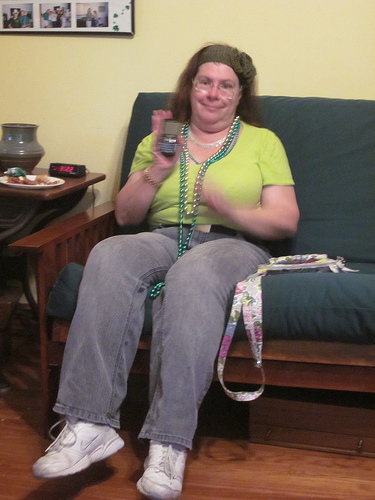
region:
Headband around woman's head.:
[200, 37, 264, 96]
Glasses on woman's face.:
[194, 73, 262, 117]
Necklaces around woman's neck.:
[177, 134, 221, 239]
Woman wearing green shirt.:
[205, 159, 258, 197]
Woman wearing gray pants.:
[73, 358, 204, 415]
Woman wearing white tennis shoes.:
[54, 423, 181, 482]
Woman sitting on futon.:
[108, 204, 297, 348]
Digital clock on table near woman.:
[53, 155, 99, 191]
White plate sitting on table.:
[8, 171, 59, 200]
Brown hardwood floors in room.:
[216, 443, 278, 478]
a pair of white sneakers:
[28, 411, 197, 499]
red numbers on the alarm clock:
[53, 160, 74, 176]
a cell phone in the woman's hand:
[156, 114, 186, 163]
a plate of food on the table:
[0, 171, 66, 192]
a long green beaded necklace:
[137, 113, 243, 303]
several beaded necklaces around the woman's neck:
[143, 111, 241, 304]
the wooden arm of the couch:
[4, 185, 119, 261]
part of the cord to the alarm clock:
[87, 175, 98, 214]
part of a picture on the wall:
[0, 0, 139, 46]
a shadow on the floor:
[14, 453, 120, 498]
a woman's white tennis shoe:
[133, 435, 191, 497]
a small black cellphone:
[156, 113, 183, 158]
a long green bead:
[146, 112, 238, 298]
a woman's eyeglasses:
[188, 69, 243, 103]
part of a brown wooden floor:
[0, 410, 373, 498]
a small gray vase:
[0, 120, 46, 172]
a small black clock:
[45, 156, 88, 176]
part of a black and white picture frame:
[0, 0, 136, 40]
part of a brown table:
[2, 163, 105, 344]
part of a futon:
[28, 86, 374, 431]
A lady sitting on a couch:
[36, 41, 268, 495]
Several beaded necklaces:
[175, 115, 242, 260]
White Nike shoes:
[31, 411, 189, 496]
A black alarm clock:
[46, 160, 88, 178]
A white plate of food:
[0, 165, 65, 192]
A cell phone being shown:
[157, 119, 182, 158]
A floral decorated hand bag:
[214, 251, 361, 412]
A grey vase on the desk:
[0, 121, 46, 173]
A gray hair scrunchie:
[196, 42, 258, 77]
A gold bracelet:
[139, 168, 162, 189]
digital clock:
[49, 161, 89, 174]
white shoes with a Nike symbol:
[32, 416, 187, 495]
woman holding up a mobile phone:
[124, 47, 267, 277]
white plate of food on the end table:
[1, 173, 59, 189]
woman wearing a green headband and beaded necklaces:
[119, 42, 301, 241]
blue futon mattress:
[303, 103, 368, 248]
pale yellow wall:
[259, 1, 368, 91]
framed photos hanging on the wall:
[1, 0, 136, 36]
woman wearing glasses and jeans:
[124, 37, 256, 314]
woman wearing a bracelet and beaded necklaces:
[115, 38, 276, 256]